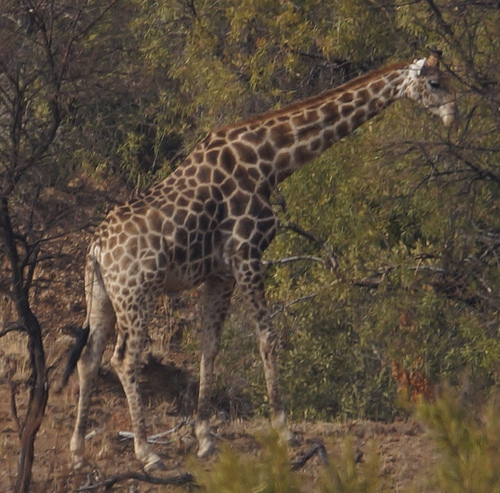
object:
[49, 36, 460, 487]
giraffe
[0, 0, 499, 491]
photograph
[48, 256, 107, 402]
tail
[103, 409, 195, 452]
branch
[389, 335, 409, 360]
leaves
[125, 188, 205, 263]
fur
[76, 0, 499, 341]
tree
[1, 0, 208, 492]
tree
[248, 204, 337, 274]
branches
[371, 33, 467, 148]
head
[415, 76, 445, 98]
eye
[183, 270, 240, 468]
legs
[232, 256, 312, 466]
legs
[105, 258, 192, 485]
legs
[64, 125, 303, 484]
body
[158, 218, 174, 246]
spots